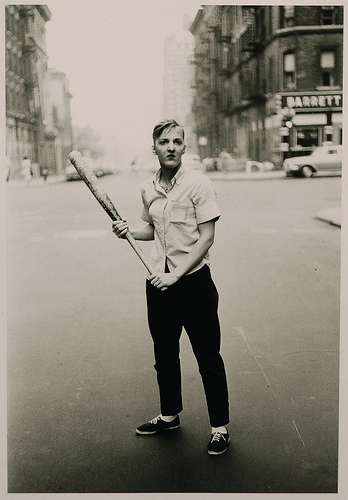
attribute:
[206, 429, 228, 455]
sneaker — black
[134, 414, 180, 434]
sneaker — black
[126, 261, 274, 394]
pants — dark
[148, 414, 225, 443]
shoe laces — white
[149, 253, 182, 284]
shirt bottom — open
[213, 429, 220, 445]
shoelaces — white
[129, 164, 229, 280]
shirt — light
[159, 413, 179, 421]
sock — white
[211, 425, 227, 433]
sock — white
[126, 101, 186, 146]
hair — short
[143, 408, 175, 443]
shoelace — white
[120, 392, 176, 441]
sneaker — dark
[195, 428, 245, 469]
sneaker — dark